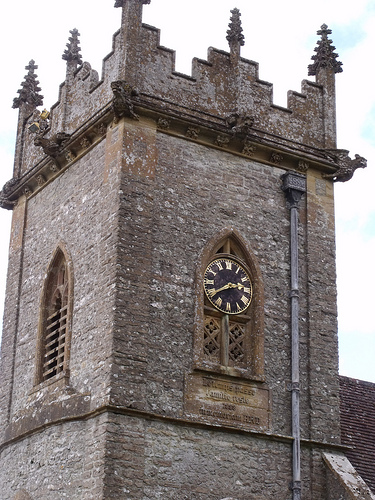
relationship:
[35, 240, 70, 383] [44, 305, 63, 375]
window has bars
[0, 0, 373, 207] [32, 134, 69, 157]
top has gargoyle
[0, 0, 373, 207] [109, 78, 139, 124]
top has decorative piece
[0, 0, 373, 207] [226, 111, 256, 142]
top has decorative piece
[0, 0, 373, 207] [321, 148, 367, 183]
top has decorative piece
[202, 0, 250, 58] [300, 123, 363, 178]
statue on building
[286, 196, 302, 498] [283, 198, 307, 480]
pipe on building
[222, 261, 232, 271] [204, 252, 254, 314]
number on clock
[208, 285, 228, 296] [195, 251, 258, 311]
hand of clock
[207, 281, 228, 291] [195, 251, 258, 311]
hand of clock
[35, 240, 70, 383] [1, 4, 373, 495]
window on tower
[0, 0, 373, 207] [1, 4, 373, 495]
top of tower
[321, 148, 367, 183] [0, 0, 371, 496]
decorative piece on building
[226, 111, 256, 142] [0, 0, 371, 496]
decorative piece on building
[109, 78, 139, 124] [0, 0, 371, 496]
decorative piece on building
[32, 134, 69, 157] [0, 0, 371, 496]
gargoyle on building